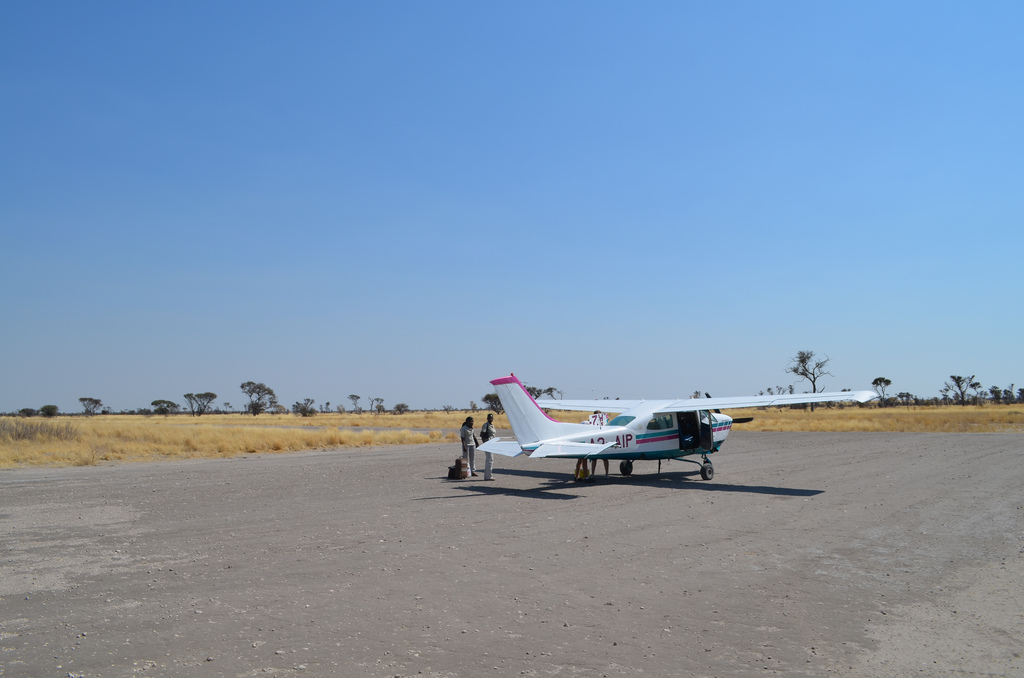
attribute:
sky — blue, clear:
[9, 22, 1014, 353]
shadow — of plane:
[452, 476, 822, 507]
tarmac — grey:
[710, 439, 907, 638]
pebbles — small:
[136, 606, 355, 676]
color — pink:
[479, 367, 538, 400]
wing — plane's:
[477, 369, 596, 450]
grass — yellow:
[10, 392, 1022, 481]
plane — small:
[445, 365, 895, 497]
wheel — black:
[700, 444, 748, 496]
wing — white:
[671, 379, 913, 438]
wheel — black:
[687, 443, 737, 491]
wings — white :
[498, 385, 916, 420]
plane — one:
[463, 359, 881, 487]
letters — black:
[603, 424, 694, 459]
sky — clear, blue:
[4, 1, 992, 412]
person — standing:
[456, 415, 483, 482]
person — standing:
[478, 407, 500, 481]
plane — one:
[463, 370, 865, 470]